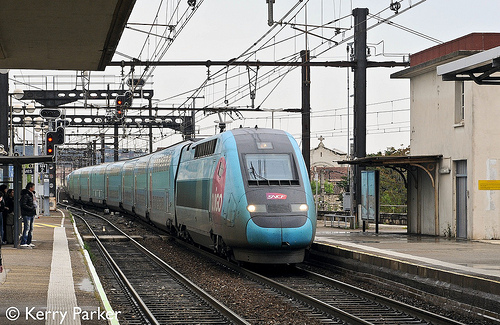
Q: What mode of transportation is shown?
A: Rail.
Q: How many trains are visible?
A: 1.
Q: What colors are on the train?
A: Blue and black.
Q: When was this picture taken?
A: Daytime.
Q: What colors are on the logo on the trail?
A: Red and white.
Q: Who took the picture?
A: Kerry Parker.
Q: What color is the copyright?
A: White.